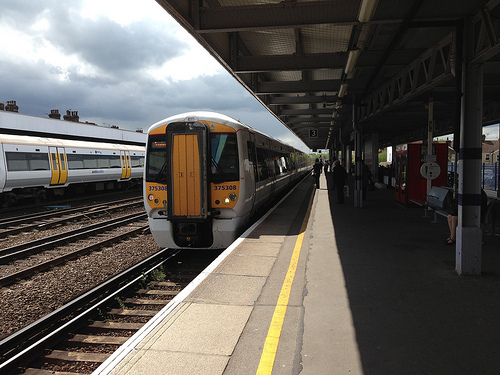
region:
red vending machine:
[388, 143, 443, 206]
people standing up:
[312, 152, 363, 201]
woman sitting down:
[446, 189, 491, 246]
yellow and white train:
[138, 107, 318, 265]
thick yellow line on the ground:
[253, 183, 327, 373]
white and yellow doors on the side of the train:
[49, 146, 69, 186]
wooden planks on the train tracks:
[34, 316, 142, 369]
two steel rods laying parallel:
[7, 290, 101, 347]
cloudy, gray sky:
[1, 2, 300, 160]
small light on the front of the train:
[223, 194, 232, 207]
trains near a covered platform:
[1, 5, 488, 350]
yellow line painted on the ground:
[255, 170, 325, 370]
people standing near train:
[191, 120, 361, 246]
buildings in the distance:
[426, 128, 497, 190]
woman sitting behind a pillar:
[415, 149, 486, 281]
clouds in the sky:
[2, 1, 289, 140]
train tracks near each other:
[2, 185, 162, 373]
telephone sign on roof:
[297, 97, 330, 149]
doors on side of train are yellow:
[33, 143, 143, 189]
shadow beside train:
[205, 130, 320, 242]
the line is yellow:
[220, 241, 310, 359]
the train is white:
[19, 117, 136, 227]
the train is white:
[39, 117, 181, 258]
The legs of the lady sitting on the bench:
[441, 213, 457, 250]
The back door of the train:
[163, 125, 213, 217]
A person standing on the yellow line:
[307, 153, 324, 189]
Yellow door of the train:
[45, 143, 71, 186]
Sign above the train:
[303, 125, 320, 145]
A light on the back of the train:
[220, 195, 235, 207]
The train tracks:
[3, 214, 132, 252]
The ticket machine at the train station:
[393, 136, 445, 206]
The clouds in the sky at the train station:
[72, 83, 238, 110]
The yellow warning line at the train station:
[262, 258, 317, 305]